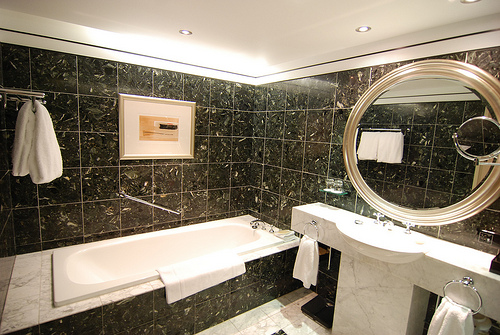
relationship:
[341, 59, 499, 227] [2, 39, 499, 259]
mirror attached to wall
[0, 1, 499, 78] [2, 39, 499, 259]
ceiling above wall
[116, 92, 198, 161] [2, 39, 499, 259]
painting attached to wall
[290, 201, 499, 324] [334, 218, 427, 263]
counter has sink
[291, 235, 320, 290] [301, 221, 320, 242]
towel hanging on ring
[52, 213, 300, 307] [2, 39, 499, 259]
bathtub next to wall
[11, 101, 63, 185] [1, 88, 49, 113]
towel hanging from pole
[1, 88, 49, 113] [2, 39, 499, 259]
pole attached to wall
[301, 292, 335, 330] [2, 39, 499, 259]
scale next to wall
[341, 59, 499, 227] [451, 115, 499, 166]
mirror next to mirror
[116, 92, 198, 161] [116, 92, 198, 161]
painting has painting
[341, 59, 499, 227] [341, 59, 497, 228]
mirror has mirror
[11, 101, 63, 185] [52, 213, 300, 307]
towel above bathtub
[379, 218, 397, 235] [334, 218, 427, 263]
facet above sink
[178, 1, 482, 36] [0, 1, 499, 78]
light on ceiling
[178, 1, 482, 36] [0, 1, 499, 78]
light in ceiling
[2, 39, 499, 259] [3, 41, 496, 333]
wall has tile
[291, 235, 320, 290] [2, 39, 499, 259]
towel next to wall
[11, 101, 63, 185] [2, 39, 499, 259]
towel next to wall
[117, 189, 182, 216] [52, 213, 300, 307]
rail above bathtub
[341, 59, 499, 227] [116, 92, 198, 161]
mirror has painting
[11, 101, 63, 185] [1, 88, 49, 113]
towel hanging o pole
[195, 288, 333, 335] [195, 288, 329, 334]
floor has tile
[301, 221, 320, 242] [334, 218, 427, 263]
ring next to sink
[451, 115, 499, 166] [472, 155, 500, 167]
mirror has swivel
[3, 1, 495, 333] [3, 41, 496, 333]
bathroom has tile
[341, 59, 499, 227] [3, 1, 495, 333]
mirror in bathroom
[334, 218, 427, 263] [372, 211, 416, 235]
sink has knobs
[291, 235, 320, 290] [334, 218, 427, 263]
towel next to sink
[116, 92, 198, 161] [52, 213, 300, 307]
painting above bathtub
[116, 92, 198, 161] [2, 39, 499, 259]
painting on wall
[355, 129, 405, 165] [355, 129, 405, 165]
towels has towels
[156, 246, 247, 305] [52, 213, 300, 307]
towel on top of bathtub